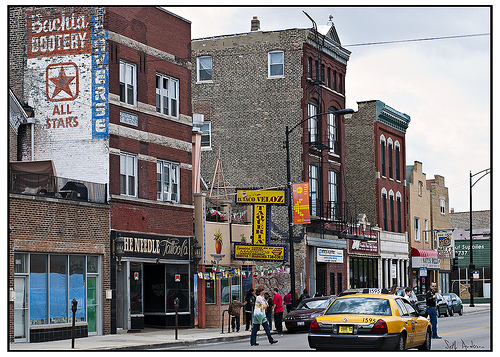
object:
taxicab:
[308, 287, 432, 354]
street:
[22, 292, 484, 353]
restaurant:
[108, 227, 202, 256]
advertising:
[125, 236, 193, 256]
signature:
[440, 335, 489, 351]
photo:
[12, 0, 499, 348]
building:
[6, 10, 202, 330]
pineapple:
[212, 228, 225, 254]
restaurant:
[194, 217, 279, 326]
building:
[184, 14, 355, 309]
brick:
[196, 17, 345, 325]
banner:
[292, 182, 310, 225]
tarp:
[28, 273, 91, 323]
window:
[28, 250, 51, 328]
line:
[439, 312, 490, 338]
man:
[271, 287, 289, 332]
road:
[424, 300, 489, 354]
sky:
[339, 6, 491, 169]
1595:
[361, 317, 376, 324]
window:
[86, 255, 100, 336]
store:
[10, 199, 111, 340]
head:
[70, 299, 78, 313]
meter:
[70, 297, 78, 353]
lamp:
[282, 108, 351, 308]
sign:
[28, 10, 111, 140]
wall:
[11, 2, 43, 162]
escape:
[315, 31, 325, 160]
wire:
[340, 30, 496, 50]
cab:
[304, 290, 436, 351]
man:
[426, 280, 442, 340]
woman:
[246, 284, 276, 345]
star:
[46, 62, 77, 100]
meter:
[173, 295, 180, 342]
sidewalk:
[11, 330, 302, 349]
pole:
[284, 127, 296, 309]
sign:
[113, 231, 202, 259]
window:
[119, 148, 137, 196]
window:
[156, 158, 181, 205]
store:
[77, 0, 217, 345]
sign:
[230, 182, 282, 261]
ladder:
[303, 198, 360, 239]